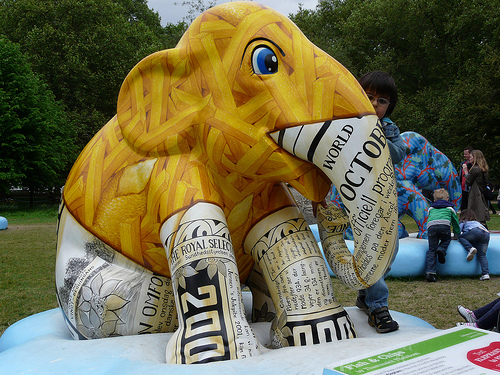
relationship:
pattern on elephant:
[165, 62, 244, 171] [89, 10, 387, 338]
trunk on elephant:
[318, 147, 405, 297] [89, 10, 387, 338]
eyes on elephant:
[236, 39, 284, 77] [89, 10, 387, 338]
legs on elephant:
[163, 231, 324, 364] [89, 10, 387, 338]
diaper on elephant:
[52, 250, 136, 324] [89, 10, 387, 338]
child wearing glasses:
[351, 68, 416, 166] [362, 97, 394, 113]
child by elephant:
[351, 68, 416, 166] [89, 10, 387, 338]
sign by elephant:
[365, 341, 467, 374] [89, 10, 387, 338]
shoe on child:
[370, 305, 396, 334] [357, 75, 406, 334]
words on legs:
[282, 251, 329, 320] [163, 231, 324, 364]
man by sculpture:
[458, 137, 469, 181] [395, 134, 461, 232]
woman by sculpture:
[465, 151, 493, 221] [395, 134, 461, 232]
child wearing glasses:
[357, 75, 406, 334] [362, 97, 394, 113]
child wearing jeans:
[357, 75, 406, 334] [372, 266, 401, 313]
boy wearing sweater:
[418, 180, 466, 285] [424, 209, 471, 229]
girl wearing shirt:
[461, 211, 493, 274] [460, 220, 483, 233]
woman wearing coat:
[465, 151, 493, 221] [474, 172, 489, 198]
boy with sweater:
[418, 180, 466, 285] [425, 201, 462, 237]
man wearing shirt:
[458, 137, 469, 181] [458, 165, 471, 187]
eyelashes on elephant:
[248, 46, 257, 80] [89, 10, 387, 338]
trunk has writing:
[318, 147, 405, 297] [360, 206, 402, 280]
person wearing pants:
[452, 286, 499, 339] [474, 299, 499, 330]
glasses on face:
[362, 97, 394, 113] [366, 96, 394, 124]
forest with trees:
[15, 30, 500, 166] [1, 18, 155, 219]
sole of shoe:
[452, 307, 470, 322] [456, 303, 481, 322]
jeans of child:
[372, 266, 401, 313] [357, 75, 406, 334]